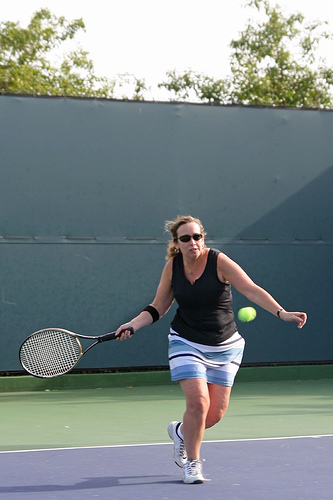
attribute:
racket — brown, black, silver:
[14, 326, 135, 381]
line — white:
[0, 433, 331, 455]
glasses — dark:
[172, 231, 207, 244]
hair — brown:
[175, 216, 189, 228]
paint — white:
[224, 438, 304, 488]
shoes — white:
[162, 418, 215, 484]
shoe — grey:
[166, 419, 185, 463]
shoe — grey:
[181, 457, 205, 483]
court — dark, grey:
[0, 436, 331, 499]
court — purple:
[7, 390, 323, 493]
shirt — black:
[162, 252, 234, 348]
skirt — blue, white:
[133, 313, 258, 378]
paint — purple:
[4, 453, 295, 498]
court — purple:
[3, 382, 331, 497]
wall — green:
[0, 114, 241, 357]